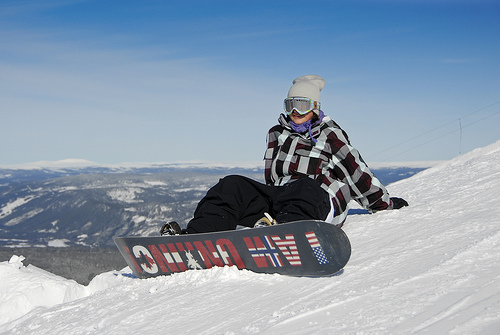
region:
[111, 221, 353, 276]
A mostly black snowboard.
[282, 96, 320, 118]
Blue goggles on the face of a person.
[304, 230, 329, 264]
Letter I on the snowboard that is red white and blue.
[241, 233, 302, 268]
The word AM on a snowboard.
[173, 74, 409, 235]
A person sitting in the snow with goggles on.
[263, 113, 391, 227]
A white, red and black checkered shirt on a person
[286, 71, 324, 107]
A grey toboggin on a persons head.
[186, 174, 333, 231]
Black pants on a person in the snow.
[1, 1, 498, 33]
Top strip of bright blue sky from left to right.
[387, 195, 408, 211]
Black glove on a left hand of a person.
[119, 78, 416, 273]
snowboarder sitting in the snow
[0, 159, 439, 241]
several mountains on the horizon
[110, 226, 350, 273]
black snowboard with writing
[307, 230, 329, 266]
american flag in shape of the letterI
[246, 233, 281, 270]
Norway flag in the shape of the letter M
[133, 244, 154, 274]
Canada flag in the shape of the letter O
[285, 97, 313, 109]
light blue rimmed goggles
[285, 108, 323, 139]
the snowboarder's purple scarf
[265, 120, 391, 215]
The showboarder's plaid sweater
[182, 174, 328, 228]
black pants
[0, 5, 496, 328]
Exterior shot, daytime, winter.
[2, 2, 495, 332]
Winter landscape, encompassing portrait of winter sport enthusiast.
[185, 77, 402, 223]
Snowboarder, reclining on snowy slope.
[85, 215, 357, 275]
Red, white and blue snowboard, with flags symbols, seen from the bottom.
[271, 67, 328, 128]
Head of snowboarder, with blue goggles and knit cap.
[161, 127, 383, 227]
Checkered shirt, black pants, and sneakers on snowboarder.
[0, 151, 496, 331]
Snowy peaks and cleft with trail marks.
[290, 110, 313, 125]
Smile on snowboarder.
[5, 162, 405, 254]
Mountains with patchy snow, in distance.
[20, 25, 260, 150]
Blue sky with thin, white clouds.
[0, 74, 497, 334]
person sitting on snow bank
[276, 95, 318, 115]
person sitting on snow bank have on snow glass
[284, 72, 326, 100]
person sitting on snow bank have on gray cap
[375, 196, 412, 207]
person sitting on snow bank have on black mitten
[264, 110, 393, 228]
person sitting on snow bank have on plat shrit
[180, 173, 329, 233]
have on black pants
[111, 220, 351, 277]
person sitting on snow bank have sky board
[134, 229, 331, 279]
boad with red,white,blue writing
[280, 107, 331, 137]
purple tie around neck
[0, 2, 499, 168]
blue sky behind him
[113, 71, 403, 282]
Snowboarder sitting on snow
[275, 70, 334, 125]
Female wearing slouchy knitted cap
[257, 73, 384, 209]
Woman wearing blue and brown coat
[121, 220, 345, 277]
Black snowboard with red, white, and blue writing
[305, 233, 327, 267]
Stars and stripes design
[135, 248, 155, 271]
Canadian maple leaf design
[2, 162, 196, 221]
Mountains in the distance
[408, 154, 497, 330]
White powdery snow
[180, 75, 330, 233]
Woman wearing black ski pants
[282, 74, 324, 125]
Woman wearing ski goggles with blue trim